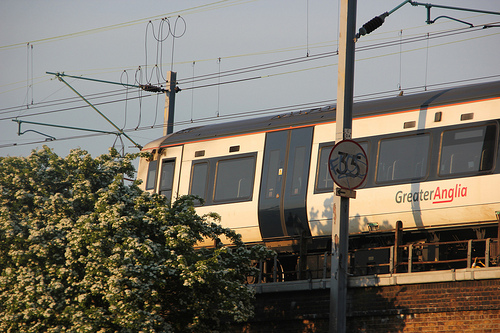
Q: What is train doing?
A: Traveling on tracks.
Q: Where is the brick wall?
A: Near metal railing.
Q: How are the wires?
A: In a bunch.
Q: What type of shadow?
A: Of a bush.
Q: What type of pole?
A: A metal pole.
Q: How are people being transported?
A: By Subway.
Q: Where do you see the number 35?
A: On a sign.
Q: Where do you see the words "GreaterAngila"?
A: On the train.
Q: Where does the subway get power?
A: Power lines.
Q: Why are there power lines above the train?
A: Power the train.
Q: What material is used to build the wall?
A: Bricks.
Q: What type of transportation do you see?
A: Subway train.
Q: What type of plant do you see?
A: A tree.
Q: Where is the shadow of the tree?
A: Brick wall.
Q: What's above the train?
A: Wires.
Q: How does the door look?
A: Tinted.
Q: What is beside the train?
A: A metal pole.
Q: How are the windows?
A: Tinted.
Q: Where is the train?
A: On elevated tracks.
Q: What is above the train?
A: Power lines.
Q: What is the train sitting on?
A: A bridge.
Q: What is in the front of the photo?
A: A green tree.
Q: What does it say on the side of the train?
A: Greater Anglia.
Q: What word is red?
A: Anglia.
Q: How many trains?
A: One.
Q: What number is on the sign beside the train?
A: 35.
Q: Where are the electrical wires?
A: Above the train.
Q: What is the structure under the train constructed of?
A: Brick.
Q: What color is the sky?
A: Gray.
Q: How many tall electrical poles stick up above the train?
A: Two.